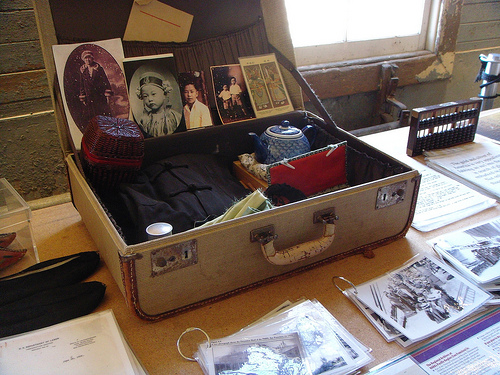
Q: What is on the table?
A: An abacus.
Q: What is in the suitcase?
A: Photographs.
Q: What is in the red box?
A: A teapot.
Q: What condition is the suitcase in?
A: Dilapidated.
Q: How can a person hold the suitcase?
A: With the handle.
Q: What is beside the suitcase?
A: A window.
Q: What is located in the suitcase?
A: Memorabilia.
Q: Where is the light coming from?
A: The window.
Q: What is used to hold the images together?
A: A ring.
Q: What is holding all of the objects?
A: A table.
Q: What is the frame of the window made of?
A: Wood.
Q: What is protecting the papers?
A: Lamination.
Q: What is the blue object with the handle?
A: A teapot.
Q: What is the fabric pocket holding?
A: A brown envelope.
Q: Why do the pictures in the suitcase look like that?
A: Antique.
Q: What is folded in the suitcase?
A: A black garment.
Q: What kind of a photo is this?
A: This is a black-and-white photograph.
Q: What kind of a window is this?
A: This is an old, shoddy window.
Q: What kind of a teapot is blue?
A: This is a ceramic pot.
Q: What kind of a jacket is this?
A: Black jacket.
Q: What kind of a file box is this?
A: Black.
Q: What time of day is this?
A: This is noon.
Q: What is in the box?
A: Photographs.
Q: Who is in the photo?
A: No one.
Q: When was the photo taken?
A: Day time.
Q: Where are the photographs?
A: In the box.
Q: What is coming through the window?
A: Light.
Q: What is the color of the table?
A: Brown.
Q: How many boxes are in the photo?
A: 1.